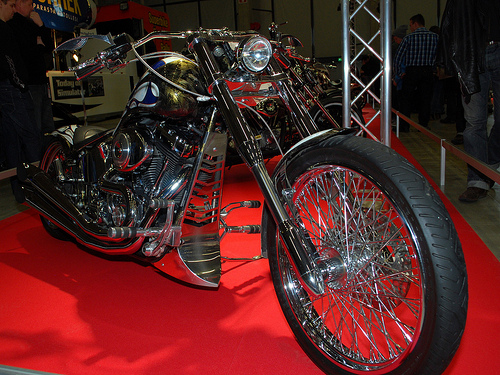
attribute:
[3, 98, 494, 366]
platform — red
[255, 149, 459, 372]
tire — black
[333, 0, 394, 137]
beams — metal, grey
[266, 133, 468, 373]
front tire — black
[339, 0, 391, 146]
pillar — metal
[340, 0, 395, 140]
post — grey, metal, support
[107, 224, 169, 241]
stand — metal, foot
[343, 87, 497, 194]
rails — guard, metal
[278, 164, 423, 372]
spokes — silver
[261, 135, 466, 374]
tire — black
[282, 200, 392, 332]
spokes — chrome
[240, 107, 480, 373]
tire — rubber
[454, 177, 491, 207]
shoes — dark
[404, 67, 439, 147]
pants — dark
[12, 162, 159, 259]
exhaust — silver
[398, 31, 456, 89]
shirt — flannel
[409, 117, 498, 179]
railing — metal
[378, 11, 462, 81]
shirt — checkered, patterned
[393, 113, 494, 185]
railing — silver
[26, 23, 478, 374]
motor bike — black, silver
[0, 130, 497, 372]
carpet — red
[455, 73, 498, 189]
pants — dark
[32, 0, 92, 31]
sign — blue, yellow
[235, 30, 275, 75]
headlight — one